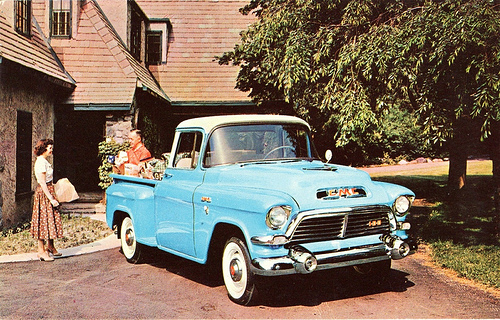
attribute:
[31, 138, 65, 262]
woman — standing up, standing, happy, talking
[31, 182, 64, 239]
skirt — patterned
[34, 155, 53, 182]
blouse — white, light colored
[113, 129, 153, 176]
man — standing, talking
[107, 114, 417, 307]
truck — blue, gmc, a pickup, parked, light blue, nice, old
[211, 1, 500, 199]
tree — big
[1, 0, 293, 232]
house — big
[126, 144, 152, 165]
shirt — orange